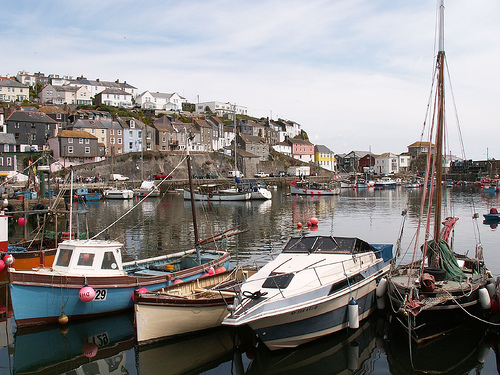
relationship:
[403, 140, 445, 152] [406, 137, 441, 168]
roof of building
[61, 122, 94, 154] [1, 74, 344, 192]
building on hill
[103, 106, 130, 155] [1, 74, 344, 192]
building on hill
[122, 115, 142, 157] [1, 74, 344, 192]
building on hill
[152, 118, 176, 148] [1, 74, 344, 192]
building on hill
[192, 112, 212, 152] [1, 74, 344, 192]
building on hill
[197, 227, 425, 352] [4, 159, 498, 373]
boat in harbor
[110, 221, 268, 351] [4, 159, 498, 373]
boat in harbor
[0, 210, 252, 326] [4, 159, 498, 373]
boat in harbor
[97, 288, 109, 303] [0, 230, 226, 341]
number on boat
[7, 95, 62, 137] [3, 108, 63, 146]
roof on building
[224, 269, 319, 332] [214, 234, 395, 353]
bow on boat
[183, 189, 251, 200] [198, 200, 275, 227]
boat on water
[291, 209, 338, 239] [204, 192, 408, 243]
fishing ball on water